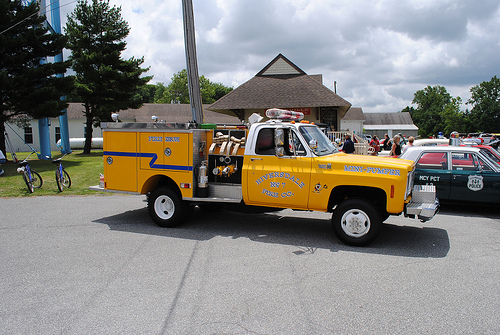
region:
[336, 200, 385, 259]
part of a wheel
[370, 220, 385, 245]
edge of a waheel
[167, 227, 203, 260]
edge of a shade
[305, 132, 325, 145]
part of a window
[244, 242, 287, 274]
part of a road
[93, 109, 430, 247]
a bright yellow truck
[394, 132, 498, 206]
a vintage green and white police car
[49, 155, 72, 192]
a blue parked bicycle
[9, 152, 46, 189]
a blue parked bicycle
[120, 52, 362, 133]
brown roofed building in distance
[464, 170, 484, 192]
white police shield logo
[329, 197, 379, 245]
truck front right tire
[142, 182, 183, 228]
truck right rear tire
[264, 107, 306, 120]
emergency flashing light bar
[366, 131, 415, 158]
group of people in parking lot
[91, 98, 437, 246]
yellow fire truck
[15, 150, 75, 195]
two bicycles parked on some grass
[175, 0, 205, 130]
fireman's ladder is vertical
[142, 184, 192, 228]
back wheel of a firetruck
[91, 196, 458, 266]
shadow of a firetruck on the ground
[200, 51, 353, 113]
pitched roof of a building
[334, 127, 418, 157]
people are wandering between parked vehicles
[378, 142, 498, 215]
police car is parked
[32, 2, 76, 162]
two tall blue poles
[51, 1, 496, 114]
sky is grey and overcast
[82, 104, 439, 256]
a yellow truck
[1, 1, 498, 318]
a scene outside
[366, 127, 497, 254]
an old fashion police car on the right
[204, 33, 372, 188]
a building in the background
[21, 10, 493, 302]
a scene during the day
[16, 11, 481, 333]
a scene on the street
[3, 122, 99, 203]
a couple of blue bikes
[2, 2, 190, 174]
a couple of green trees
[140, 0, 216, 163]
a grey pole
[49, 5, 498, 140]
a sky with clouds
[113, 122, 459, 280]
a yellow fire truck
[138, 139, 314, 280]
a yellow fire truck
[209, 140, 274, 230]
a yellow fire truck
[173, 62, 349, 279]
a yellow fire truck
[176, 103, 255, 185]
a yellow fire truck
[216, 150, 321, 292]
a yellow fire truck